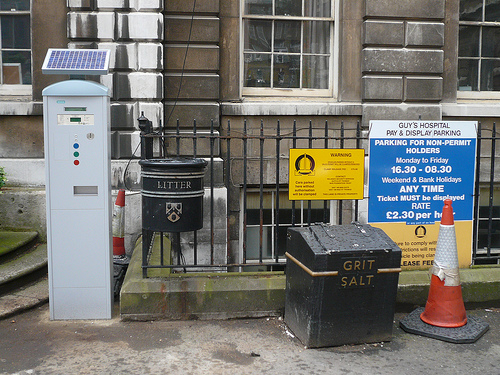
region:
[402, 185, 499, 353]
safety cone on sidewalk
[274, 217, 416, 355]
black salt box on sidewalk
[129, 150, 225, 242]
litter box on fence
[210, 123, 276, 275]
black iron fence by sidewalk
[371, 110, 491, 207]
sign along side of fence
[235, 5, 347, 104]
windows of a building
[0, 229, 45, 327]
concrete steps to a building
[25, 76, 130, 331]
ticket meter on sidewalk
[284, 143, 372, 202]
yellow warning sign on fence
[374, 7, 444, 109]
brick wall of a building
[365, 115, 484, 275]
parking information sign on gate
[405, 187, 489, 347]
orange colored construction cone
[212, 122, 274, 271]
wrought iron small fence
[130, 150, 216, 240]
small black litter can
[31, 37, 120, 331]
automated parking pass machine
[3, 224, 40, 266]
moss covered rounded steps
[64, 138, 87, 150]
blue button on parking pass machine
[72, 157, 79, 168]
red button on parking pass machine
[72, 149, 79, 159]
green button on parking pass machine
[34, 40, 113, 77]
solar power panel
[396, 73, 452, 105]
grey brick on a building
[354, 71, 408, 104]
grey brick on a building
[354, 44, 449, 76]
grey brick on a building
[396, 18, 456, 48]
grey brick on a building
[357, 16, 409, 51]
grey brick on a building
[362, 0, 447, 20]
grey brick on a building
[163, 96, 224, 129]
grey brick on a building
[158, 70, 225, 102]
grey brick on a building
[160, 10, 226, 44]
grey brick on a building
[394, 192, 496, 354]
orange and black safety cone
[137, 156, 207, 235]
a black litter can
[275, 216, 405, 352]
a black salt container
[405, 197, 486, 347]
an orange and white safety cone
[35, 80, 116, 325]
a tall white electronic parking box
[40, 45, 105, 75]
a small solar panel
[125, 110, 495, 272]
a wrought iron fence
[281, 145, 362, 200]
a yellow informational sign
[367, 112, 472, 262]
a white blue and yellow informational sign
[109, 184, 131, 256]
an orange and white safety cone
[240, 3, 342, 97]
a white framed window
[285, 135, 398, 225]
the sign is yellow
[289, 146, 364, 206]
sign has black lettering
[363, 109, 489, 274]
sign is blue and white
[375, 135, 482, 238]
sign has white lettering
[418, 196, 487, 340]
cone is orange and white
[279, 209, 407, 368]
the object is black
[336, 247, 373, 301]
object has gold lettering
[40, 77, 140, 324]
the object is white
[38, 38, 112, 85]
solar panel on object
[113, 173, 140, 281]
orange cone behind object